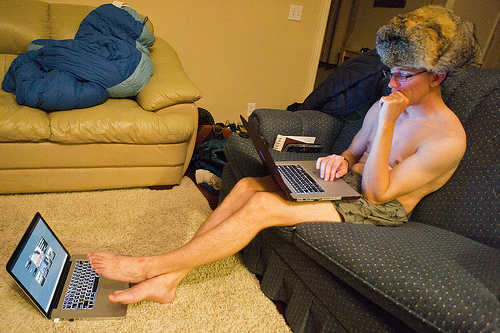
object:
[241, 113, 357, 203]
laptop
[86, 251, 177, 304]
feet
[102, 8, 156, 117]
sleeping bag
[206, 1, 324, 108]
wall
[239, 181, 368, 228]
lap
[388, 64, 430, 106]
face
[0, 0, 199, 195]
couch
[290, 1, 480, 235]
man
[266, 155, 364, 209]
laptop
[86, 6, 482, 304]
man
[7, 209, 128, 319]
laptop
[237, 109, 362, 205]
laptop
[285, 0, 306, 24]
light switch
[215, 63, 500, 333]
couch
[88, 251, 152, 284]
foot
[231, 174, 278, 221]
knee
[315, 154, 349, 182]
hand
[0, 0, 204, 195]
couch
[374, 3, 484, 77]
hat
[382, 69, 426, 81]
glasses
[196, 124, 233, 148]
backpack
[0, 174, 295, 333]
rug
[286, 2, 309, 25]
switches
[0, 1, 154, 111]
blanket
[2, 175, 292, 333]
carpet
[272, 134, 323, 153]
papers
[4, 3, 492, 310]
room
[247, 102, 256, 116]
outlet